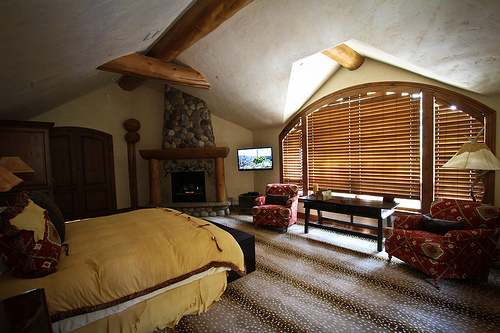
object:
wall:
[218, 59, 443, 198]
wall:
[29, 81, 159, 137]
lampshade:
[441, 141, 500, 171]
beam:
[320, 45, 366, 71]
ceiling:
[1, 0, 500, 54]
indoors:
[217, 103, 473, 233]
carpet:
[155, 267, 499, 332]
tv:
[236, 146, 273, 171]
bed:
[0, 205, 247, 333]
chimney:
[161, 85, 217, 149]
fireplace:
[139, 146, 231, 217]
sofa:
[251, 183, 299, 233]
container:
[202, 217, 256, 284]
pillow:
[414, 214, 466, 237]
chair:
[382, 197, 499, 293]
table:
[297, 193, 401, 252]